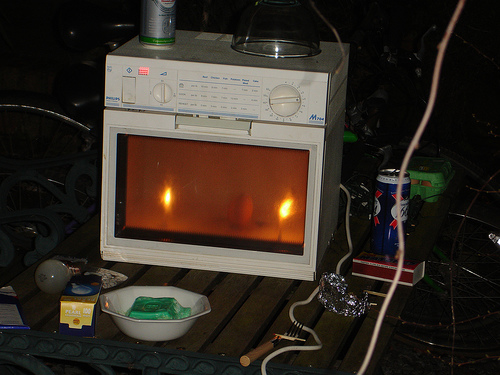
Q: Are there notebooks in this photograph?
A: No, there are no notebooks.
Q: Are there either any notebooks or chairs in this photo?
A: No, there are no notebooks or chairs.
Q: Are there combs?
A: No, there are no combs.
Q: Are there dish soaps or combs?
A: No, there are no combs or dish soaps.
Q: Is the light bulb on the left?
A: Yes, the light bulb is on the left of the image.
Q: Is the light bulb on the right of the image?
A: No, the light bulb is on the left of the image.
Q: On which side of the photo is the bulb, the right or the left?
A: The bulb is on the left of the image.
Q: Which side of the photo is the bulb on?
A: The bulb is on the left of the image.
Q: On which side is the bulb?
A: The bulb is on the left of the image.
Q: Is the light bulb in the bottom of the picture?
A: Yes, the light bulb is in the bottom of the image.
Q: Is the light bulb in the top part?
A: No, the light bulb is in the bottom of the image.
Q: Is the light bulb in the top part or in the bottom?
A: The light bulb is in the bottom of the image.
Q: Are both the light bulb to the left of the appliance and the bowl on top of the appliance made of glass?
A: Yes, both the bulb and the bowl are made of glass.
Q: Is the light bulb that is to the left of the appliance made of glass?
A: Yes, the bulb is made of glass.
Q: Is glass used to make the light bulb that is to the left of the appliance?
A: Yes, the bulb is made of glass.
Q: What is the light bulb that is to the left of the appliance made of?
A: The light bulb is made of glass.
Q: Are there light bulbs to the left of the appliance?
A: Yes, there is a light bulb to the left of the appliance.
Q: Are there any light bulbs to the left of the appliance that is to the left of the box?
A: Yes, there is a light bulb to the left of the appliance.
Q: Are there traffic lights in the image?
A: No, there are no traffic lights.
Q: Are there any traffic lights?
A: No, there are no traffic lights.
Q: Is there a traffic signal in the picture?
A: No, there are no traffic lights.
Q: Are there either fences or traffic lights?
A: No, there are no traffic lights or fences.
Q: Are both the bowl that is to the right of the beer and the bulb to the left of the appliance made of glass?
A: Yes, both the bowl and the light bulb are made of glass.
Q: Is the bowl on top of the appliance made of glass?
A: Yes, the bowl is made of glass.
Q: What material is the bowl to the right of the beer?
A: The bowl is made of glass.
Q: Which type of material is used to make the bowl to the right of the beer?
A: The bowl is made of glass.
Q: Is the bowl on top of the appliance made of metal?
A: No, the bowl is made of glass.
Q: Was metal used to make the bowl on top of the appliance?
A: No, the bowl is made of glass.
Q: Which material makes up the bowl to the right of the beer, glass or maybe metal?
A: The bowl is made of glass.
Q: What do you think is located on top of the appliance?
A: The bowl is on top of the appliance.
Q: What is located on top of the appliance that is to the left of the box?
A: The bowl is on top of the appliance.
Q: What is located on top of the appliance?
A: The bowl is on top of the appliance.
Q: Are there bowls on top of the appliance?
A: Yes, there is a bowl on top of the appliance.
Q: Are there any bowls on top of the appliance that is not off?
A: Yes, there is a bowl on top of the appliance.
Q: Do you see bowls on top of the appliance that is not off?
A: Yes, there is a bowl on top of the appliance.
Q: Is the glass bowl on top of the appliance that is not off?
A: Yes, the bowl is on top of the appliance.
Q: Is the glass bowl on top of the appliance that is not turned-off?
A: Yes, the bowl is on top of the appliance.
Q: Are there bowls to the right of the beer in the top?
A: Yes, there is a bowl to the right of the beer.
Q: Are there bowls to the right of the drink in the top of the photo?
A: Yes, there is a bowl to the right of the beer.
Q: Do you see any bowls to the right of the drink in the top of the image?
A: Yes, there is a bowl to the right of the beer.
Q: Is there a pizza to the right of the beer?
A: No, there is a bowl to the right of the beer.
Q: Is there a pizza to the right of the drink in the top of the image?
A: No, there is a bowl to the right of the beer.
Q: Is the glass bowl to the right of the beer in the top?
A: Yes, the bowl is to the right of the beer.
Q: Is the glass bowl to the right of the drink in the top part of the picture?
A: Yes, the bowl is to the right of the beer.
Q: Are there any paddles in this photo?
A: No, there are no paddles.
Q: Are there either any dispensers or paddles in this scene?
A: No, there are no paddles or dispensers.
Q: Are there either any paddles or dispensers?
A: No, there are no paddles or dispensers.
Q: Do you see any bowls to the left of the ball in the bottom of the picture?
A: Yes, there is a bowl to the left of the ball.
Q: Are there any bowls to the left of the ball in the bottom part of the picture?
A: Yes, there is a bowl to the left of the ball.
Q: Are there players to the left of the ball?
A: No, there is a bowl to the left of the ball.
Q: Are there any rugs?
A: No, there are no rugs.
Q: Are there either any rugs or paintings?
A: No, there are no rugs or paintings.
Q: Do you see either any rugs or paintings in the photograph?
A: No, there are no rugs or paintings.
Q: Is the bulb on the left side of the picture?
A: Yes, the bulb is on the left of the image.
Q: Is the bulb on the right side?
A: No, the bulb is on the left of the image.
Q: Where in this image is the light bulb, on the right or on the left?
A: The light bulb is on the left of the image.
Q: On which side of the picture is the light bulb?
A: The light bulb is on the left of the image.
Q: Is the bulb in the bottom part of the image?
A: Yes, the bulb is in the bottom of the image.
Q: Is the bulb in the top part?
A: No, the bulb is in the bottom of the image.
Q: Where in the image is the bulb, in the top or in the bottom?
A: The bulb is in the bottom of the image.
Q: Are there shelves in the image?
A: No, there are no shelves.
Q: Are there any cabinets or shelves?
A: No, there are no shelves or cabinets.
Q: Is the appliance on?
A: Yes, the appliance is on.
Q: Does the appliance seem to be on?
A: Yes, the appliance is on.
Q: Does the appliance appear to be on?
A: Yes, the appliance is on.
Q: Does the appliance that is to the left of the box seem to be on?
A: Yes, the appliance is on.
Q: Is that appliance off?
A: No, the appliance is on.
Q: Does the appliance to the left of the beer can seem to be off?
A: No, the appliance is on.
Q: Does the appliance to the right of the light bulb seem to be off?
A: No, the appliance is on.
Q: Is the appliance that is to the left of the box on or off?
A: The appliance is on.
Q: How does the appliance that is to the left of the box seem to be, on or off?
A: The appliance is on.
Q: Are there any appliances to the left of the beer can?
A: Yes, there is an appliance to the left of the beer can.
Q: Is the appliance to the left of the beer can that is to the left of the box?
A: Yes, the appliance is to the left of the beer can.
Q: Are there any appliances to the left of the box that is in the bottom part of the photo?
A: Yes, there is an appliance to the left of the box.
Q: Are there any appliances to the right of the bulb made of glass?
A: Yes, there is an appliance to the right of the bulb.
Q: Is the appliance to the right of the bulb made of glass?
A: Yes, the appliance is to the right of the bulb.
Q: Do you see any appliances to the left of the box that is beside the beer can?
A: Yes, there is an appliance to the left of the box.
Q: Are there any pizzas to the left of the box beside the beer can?
A: No, there is an appliance to the left of the box.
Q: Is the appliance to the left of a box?
A: Yes, the appliance is to the left of a box.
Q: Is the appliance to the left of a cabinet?
A: No, the appliance is to the left of a box.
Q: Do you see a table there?
A: Yes, there is a table.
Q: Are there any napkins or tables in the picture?
A: Yes, there is a table.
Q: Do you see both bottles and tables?
A: No, there is a table but no bottles.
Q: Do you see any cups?
A: No, there are no cups.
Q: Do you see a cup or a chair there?
A: No, there are no cups or chairs.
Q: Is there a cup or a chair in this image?
A: No, there are no cups or chairs.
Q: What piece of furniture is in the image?
A: The piece of furniture is a table.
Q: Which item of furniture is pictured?
A: The piece of furniture is a table.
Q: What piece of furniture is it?
A: The piece of furniture is a table.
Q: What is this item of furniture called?
A: This is a table.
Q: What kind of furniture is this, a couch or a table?
A: This is a table.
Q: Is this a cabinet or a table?
A: This is a table.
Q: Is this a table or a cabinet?
A: This is a table.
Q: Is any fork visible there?
A: Yes, there is a fork.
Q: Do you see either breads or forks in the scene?
A: Yes, there is a fork.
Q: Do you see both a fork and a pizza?
A: No, there is a fork but no pizzas.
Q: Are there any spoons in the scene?
A: No, there are no spoons.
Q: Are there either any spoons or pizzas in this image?
A: No, there are no spoons or pizzas.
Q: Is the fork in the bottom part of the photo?
A: Yes, the fork is in the bottom of the image.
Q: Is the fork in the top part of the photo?
A: No, the fork is in the bottom of the image.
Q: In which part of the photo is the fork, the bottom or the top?
A: The fork is in the bottom of the image.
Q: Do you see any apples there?
A: No, there are no apples.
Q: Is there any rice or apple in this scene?
A: No, there are no apples or rice.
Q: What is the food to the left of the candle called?
A: The food is an egg.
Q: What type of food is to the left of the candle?
A: The food is an egg.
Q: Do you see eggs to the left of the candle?
A: Yes, there is an egg to the left of the candle.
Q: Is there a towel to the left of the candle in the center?
A: No, there is an egg to the left of the candle.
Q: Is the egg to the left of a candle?
A: Yes, the egg is to the left of a candle.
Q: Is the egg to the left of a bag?
A: No, the egg is to the left of a candle.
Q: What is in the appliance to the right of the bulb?
A: The egg is in the appliance.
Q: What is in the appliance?
A: The egg is in the appliance.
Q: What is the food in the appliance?
A: The food is an egg.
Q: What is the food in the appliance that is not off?
A: The food is an egg.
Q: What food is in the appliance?
A: The food is an egg.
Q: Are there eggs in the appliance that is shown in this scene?
A: Yes, there is an egg in the appliance.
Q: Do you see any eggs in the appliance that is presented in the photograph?
A: Yes, there is an egg in the appliance.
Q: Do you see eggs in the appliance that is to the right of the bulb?
A: Yes, there is an egg in the appliance.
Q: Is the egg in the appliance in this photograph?
A: Yes, the egg is in the appliance.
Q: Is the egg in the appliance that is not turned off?
A: Yes, the egg is in the appliance.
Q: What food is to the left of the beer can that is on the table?
A: The food is an egg.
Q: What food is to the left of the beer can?
A: The food is an egg.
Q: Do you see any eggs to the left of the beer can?
A: Yes, there is an egg to the left of the beer can.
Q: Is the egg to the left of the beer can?
A: Yes, the egg is to the left of the beer can.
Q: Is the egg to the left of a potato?
A: No, the egg is to the left of the beer can.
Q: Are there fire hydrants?
A: No, there are no fire hydrants.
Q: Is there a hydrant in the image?
A: No, there are no fire hydrants.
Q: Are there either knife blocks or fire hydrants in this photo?
A: No, there are no fire hydrants or knife blocks.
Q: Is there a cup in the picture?
A: No, there are no cups.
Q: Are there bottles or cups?
A: No, there are no cups or bottles.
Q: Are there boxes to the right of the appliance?
A: Yes, there is a box to the right of the appliance.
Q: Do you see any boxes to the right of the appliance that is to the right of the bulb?
A: Yes, there is a box to the right of the appliance.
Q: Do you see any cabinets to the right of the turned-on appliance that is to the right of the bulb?
A: No, there is a box to the right of the appliance.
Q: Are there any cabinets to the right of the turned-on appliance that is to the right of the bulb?
A: No, there is a box to the right of the appliance.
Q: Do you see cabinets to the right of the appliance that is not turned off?
A: No, there is a box to the right of the appliance.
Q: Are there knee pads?
A: No, there are no knee pads.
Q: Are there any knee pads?
A: No, there are no knee pads.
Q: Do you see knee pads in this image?
A: No, there are no knee pads.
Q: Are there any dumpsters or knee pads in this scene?
A: No, there are no knee pads or dumpsters.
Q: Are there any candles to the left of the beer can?
A: Yes, there is a candle to the left of the beer can.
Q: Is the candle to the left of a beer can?
A: Yes, the candle is to the left of a beer can.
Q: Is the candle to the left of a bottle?
A: No, the candle is to the left of a beer can.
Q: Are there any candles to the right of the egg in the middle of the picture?
A: Yes, there is a candle to the right of the egg.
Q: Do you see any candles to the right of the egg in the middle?
A: Yes, there is a candle to the right of the egg.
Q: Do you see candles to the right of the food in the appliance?
A: Yes, there is a candle to the right of the egg.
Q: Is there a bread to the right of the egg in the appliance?
A: No, there is a candle to the right of the egg.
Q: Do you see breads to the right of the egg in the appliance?
A: No, there is a candle to the right of the egg.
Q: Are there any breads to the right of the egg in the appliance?
A: No, there is a candle to the right of the egg.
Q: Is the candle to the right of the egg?
A: Yes, the candle is to the right of the egg.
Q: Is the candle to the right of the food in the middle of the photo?
A: Yes, the candle is to the right of the egg.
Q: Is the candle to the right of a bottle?
A: No, the candle is to the right of the egg.